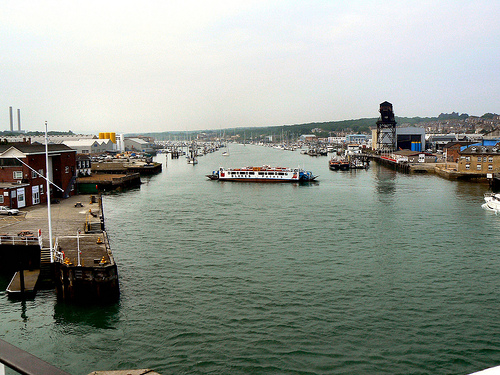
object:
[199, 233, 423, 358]
water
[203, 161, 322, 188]
boat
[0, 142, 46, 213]
house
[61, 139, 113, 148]
roof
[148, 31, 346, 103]
sky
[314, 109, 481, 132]
hill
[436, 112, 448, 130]
tress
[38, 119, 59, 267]
pole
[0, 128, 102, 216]
building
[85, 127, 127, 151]
houses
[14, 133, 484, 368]
water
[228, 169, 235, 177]
windows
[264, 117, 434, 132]
hillside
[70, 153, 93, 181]
building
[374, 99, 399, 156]
building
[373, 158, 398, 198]
shadow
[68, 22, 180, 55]
clouds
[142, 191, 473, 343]
water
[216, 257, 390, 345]
ripples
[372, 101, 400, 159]
tower